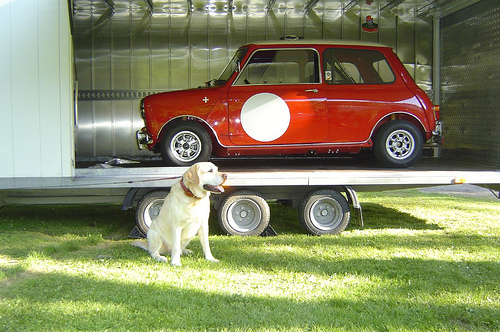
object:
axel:
[299, 187, 351, 236]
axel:
[217, 188, 272, 237]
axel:
[134, 189, 169, 238]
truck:
[0, 0, 500, 238]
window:
[323, 48, 395, 84]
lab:
[128, 152, 239, 272]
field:
[0, 184, 500, 332]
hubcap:
[227, 199, 262, 233]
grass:
[0, 189, 500, 331]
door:
[227, 44, 329, 146]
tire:
[374, 119, 423, 168]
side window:
[232, 48, 321, 86]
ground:
[0, 190, 500, 332]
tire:
[161, 121, 213, 167]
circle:
[240, 93, 291, 143]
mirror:
[236, 61, 240, 73]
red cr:
[136, 35, 441, 167]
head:
[182, 162, 228, 195]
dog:
[128, 161, 228, 266]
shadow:
[0, 202, 500, 332]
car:
[135, 34, 444, 168]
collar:
[180, 178, 196, 197]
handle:
[304, 89, 318, 93]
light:
[433, 105, 440, 121]